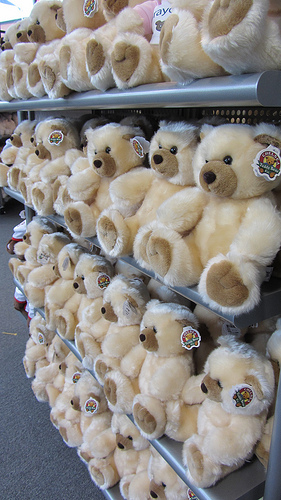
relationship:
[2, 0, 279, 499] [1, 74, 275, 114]
bears on a shelf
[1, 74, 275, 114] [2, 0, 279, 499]
shelf holds some bears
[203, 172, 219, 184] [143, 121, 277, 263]
nose on a bear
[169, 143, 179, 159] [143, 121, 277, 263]
eye on a bear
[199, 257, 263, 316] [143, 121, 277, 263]
foot on a bear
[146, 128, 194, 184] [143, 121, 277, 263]
face on a bear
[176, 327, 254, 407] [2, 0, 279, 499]
tags on bears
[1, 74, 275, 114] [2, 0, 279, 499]
shelf full of bears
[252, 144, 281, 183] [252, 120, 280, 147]
tag on bears ear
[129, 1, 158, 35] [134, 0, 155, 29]
shirt on one bear pink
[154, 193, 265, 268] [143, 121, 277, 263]
paws on a bear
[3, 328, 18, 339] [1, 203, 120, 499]
yellow strip on floor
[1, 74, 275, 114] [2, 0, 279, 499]
shelf of bears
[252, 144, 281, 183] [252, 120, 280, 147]
tag on an ear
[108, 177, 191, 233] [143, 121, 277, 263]
paws on a bear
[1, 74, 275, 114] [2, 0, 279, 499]
shelf under bears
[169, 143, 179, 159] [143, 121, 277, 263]
eye of a bear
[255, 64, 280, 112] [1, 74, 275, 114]
edge of shelf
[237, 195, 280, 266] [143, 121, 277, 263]
arm os a bear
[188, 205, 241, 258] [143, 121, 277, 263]
belly on a bear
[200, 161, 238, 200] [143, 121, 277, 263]
muzzle of a bear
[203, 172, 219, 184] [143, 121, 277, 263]
nose of a bear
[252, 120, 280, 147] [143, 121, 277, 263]
ear of a bear